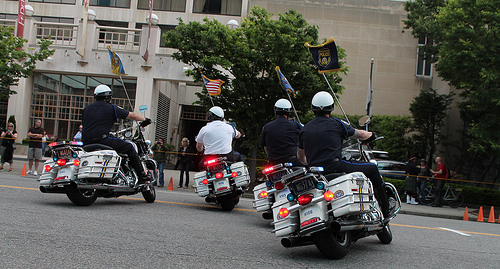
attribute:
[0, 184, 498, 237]
yellow line — yellow 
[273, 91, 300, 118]
helmet — white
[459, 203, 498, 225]
cones — three orange traffic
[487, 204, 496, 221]
cone — orange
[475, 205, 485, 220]
cone — orange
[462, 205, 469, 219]
cone — orange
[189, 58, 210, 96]
pole — silver flag 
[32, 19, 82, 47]
railing — brown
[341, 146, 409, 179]
vehicle — parked 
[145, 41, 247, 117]
flag — red, white, blue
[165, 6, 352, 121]
bush — large, green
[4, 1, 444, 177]
building — tan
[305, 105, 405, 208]
police officer — short-sleeved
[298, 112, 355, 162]
shirt — dark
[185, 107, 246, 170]
shirt — white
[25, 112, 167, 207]
white motorcycle — large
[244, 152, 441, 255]
motorcycle — white, large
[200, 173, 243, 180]
brakelights — light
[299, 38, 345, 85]
flag — yellow , navy blue 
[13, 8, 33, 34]
sign — Red 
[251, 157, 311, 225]
motorcycle — large, white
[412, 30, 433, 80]
window — part 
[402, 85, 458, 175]
tree — small 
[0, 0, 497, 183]
building — side 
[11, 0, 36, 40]
flag — red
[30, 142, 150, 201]
motorcycle — white, green, black, red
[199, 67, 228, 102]
flag — American 